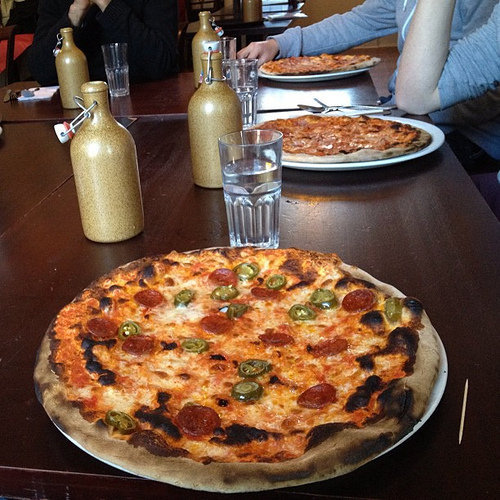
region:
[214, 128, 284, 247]
a clear glass of water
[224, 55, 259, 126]
a clear glass of water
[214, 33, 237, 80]
a clear glass of water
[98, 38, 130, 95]
a clear glass of water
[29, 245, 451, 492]
a whole pizza pie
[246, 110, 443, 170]
a whole pizza pie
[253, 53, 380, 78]
a whole pizza pie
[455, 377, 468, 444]
a brown wood toothpick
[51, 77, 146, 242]
a gold glass bottle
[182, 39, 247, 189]
a gold glass bottle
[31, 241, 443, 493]
Round pizza on round white plate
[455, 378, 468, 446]
Toothpick next to pizza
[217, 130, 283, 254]
Glass of water next to pizza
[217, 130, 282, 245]
Glass of water on wooden table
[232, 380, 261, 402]
Jalapeno on round pizza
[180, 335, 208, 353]
Jalapeno on round pizza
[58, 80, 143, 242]
Small olive green jar bottle on wooden table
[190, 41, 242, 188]
Small olive green jar bottle next to pizza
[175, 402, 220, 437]
Round pepperoni slice on pizza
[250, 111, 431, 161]
Round pizza on round white plate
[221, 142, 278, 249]
the glass has water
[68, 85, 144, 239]
the bottle is brown in colour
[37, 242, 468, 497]
the pasta is in the plate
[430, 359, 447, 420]
the plate is white in colour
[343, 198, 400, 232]
the table is brown in colour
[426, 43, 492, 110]
the jumper is folded at the arms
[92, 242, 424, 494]
ththe pasta has red black and green colours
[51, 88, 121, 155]
the bottle is tied at the brim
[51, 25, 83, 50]
the bottle has a narrow brim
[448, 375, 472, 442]
a toothpick is on the table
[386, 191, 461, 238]
this is a table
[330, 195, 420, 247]
the table is brown in color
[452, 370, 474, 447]
this is a toothpick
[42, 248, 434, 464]
this is a pizza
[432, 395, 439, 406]
this is a plate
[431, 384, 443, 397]
the plate is white in color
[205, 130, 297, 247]
this is a glass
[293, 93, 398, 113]
this is a fork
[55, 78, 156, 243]
this is a bottle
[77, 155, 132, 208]
the bottle is metallic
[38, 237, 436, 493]
a pizza pie is on a dish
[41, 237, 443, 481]
the pizza is round in shape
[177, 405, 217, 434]
pepperoni is on the pizza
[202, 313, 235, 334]
pepperoni is on the pizza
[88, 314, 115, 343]
pepperoni is on the pizza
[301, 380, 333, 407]
pepperoni is on the pizza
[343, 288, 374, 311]
pepperoni is on the pizza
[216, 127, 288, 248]
a glass is on the table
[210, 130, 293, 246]
the glass is filled with water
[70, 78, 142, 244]
the bottle is metallic gold in color